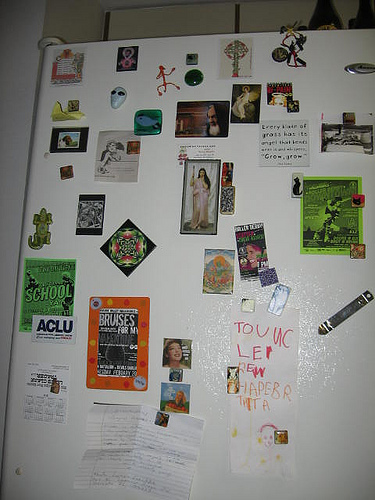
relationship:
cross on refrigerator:
[216, 34, 255, 79] [2, 23, 374, 493]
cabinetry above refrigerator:
[60, 3, 372, 38] [2, 23, 374, 493]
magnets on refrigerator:
[7, 34, 373, 438] [2, 23, 374, 493]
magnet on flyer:
[110, 84, 126, 113] [294, 174, 364, 259]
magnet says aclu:
[110, 84, 126, 113] [36, 313, 74, 334]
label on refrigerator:
[340, 56, 372, 80] [2, 23, 374, 493]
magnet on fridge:
[110, 84, 126, 113] [4, 27, 373, 497]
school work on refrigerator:
[77, 397, 216, 499] [2, 23, 374, 493]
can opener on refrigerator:
[310, 288, 374, 338] [2, 23, 374, 493]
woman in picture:
[189, 163, 212, 228] [163, 336, 195, 365]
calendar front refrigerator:
[14, 358, 73, 431] [2, 23, 374, 493]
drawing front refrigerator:
[225, 300, 297, 475] [2, 23, 374, 493]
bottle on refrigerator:
[304, 0, 340, 29] [2, 23, 374, 493]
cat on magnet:
[288, 172, 305, 197] [110, 84, 126, 113]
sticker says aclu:
[29, 312, 78, 344] [33, 312, 78, 333]